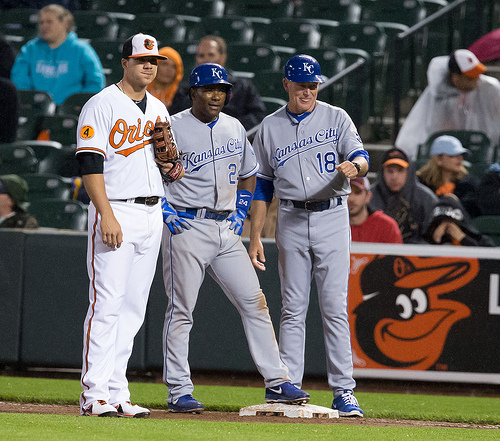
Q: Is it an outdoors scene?
A: Yes, it is outdoors.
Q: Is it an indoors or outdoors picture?
A: It is outdoors.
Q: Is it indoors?
A: No, it is outdoors.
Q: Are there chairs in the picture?
A: Yes, there is a chair.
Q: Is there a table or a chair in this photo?
A: Yes, there is a chair.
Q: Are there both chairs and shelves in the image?
A: No, there is a chair but no shelves.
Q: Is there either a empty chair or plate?
A: Yes, there is an empty chair.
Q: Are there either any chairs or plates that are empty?
A: Yes, the chair is empty.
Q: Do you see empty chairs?
A: Yes, there is an empty chair.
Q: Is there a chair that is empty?
A: Yes, there is a chair that is empty.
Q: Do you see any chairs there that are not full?
A: Yes, there is a empty chair.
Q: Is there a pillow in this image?
A: No, there are no pillows.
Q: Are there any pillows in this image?
A: No, there are no pillows.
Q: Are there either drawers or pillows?
A: No, there are no pillows or drawers.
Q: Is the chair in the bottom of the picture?
A: No, the chair is in the top of the image.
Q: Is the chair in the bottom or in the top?
A: The chair is in the top of the image.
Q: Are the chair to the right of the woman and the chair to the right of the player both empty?
A: Yes, both the chair and the chair are empty.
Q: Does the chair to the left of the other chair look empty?
A: Yes, the chair is empty.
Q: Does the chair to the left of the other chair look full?
A: No, the chair is empty.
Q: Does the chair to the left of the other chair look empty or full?
A: The chair is empty.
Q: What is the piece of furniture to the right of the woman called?
A: The piece of furniture is a chair.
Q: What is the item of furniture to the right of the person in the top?
A: The piece of furniture is a chair.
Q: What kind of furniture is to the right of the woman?
A: The piece of furniture is a chair.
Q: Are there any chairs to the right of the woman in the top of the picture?
A: Yes, there is a chair to the right of the woman.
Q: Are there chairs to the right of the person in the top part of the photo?
A: Yes, there is a chair to the right of the woman.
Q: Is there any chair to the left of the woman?
A: No, the chair is to the right of the woman.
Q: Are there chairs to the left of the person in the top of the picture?
A: No, the chair is to the right of the woman.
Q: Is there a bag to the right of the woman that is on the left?
A: No, there is a chair to the right of the woman.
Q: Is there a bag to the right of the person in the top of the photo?
A: No, there is a chair to the right of the woman.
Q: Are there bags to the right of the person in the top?
A: No, there is a chair to the right of the woman.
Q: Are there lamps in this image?
A: No, there are no lamps.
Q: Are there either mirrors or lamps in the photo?
A: No, there are no lamps or mirrors.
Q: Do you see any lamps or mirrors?
A: No, there are no lamps or mirrors.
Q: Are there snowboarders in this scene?
A: No, there are no snowboarders.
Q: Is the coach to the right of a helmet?
A: Yes, the coach is to the right of a helmet.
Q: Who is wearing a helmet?
A: The coach is wearing a helmet.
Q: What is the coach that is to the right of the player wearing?
A: The coach is wearing a helmet.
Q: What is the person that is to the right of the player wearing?
A: The coach is wearing a helmet.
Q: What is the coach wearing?
A: The coach is wearing a helmet.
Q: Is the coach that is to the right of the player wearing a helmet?
A: Yes, the coach is wearing a helmet.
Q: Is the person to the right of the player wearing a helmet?
A: Yes, the coach is wearing a helmet.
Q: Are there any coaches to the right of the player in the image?
A: Yes, there is a coach to the right of the player.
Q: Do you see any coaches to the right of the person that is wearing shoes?
A: Yes, there is a coach to the right of the player.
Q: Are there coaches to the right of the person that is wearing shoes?
A: Yes, there is a coach to the right of the player.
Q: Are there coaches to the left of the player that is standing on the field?
A: No, the coach is to the right of the player.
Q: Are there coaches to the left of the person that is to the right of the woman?
A: No, the coach is to the right of the player.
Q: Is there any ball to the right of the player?
A: No, there is a coach to the right of the player.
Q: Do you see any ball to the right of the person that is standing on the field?
A: No, there is a coach to the right of the player.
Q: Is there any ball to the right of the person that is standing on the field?
A: No, there is a coach to the right of the player.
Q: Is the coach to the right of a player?
A: Yes, the coach is to the right of a player.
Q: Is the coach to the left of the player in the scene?
A: No, the coach is to the right of the player.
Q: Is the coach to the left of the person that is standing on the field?
A: No, the coach is to the right of the player.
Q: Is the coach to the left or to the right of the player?
A: The coach is to the right of the player.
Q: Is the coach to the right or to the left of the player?
A: The coach is to the right of the player.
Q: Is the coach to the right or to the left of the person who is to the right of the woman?
A: The coach is to the right of the player.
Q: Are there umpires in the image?
A: No, there are no umpires.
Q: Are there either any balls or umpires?
A: No, there are no umpires or balls.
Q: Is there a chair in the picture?
A: Yes, there is a chair.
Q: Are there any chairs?
A: Yes, there is a chair.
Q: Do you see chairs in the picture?
A: Yes, there is a chair.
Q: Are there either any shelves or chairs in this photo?
A: Yes, there is a chair.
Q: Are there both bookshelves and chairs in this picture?
A: No, there is a chair but no bookshelves.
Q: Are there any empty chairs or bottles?
A: Yes, there is an empty chair.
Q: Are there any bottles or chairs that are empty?
A: Yes, the chair is empty.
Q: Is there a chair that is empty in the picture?
A: Yes, there is an empty chair.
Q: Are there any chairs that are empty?
A: Yes, there is a chair that is empty.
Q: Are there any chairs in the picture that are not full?
A: Yes, there is a empty chair.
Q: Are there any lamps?
A: No, there are no lamps.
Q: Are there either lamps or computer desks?
A: No, there are no lamps or computer desks.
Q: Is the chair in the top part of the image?
A: Yes, the chair is in the top of the image.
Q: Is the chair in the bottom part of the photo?
A: No, the chair is in the top of the image.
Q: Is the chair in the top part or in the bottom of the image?
A: The chair is in the top of the image.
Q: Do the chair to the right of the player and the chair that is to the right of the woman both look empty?
A: Yes, both the chair and the chair are empty.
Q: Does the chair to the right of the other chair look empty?
A: Yes, the chair is empty.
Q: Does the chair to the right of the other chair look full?
A: No, the chair is empty.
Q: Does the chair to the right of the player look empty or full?
A: The chair is empty.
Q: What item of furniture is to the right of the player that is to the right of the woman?
A: The piece of furniture is a chair.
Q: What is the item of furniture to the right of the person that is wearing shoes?
A: The piece of furniture is a chair.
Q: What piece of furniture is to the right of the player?
A: The piece of furniture is a chair.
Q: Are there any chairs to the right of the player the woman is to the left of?
A: Yes, there is a chair to the right of the player.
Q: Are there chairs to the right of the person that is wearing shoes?
A: Yes, there is a chair to the right of the player.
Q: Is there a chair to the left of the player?
A: No, the chair is to the right of the player.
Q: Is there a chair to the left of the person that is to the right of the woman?
A: No, the chair is to the right of the player.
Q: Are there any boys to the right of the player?
A: No, there is a chair to the right of the player.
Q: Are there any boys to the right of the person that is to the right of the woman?
A: No, there is a chair to the right of the player.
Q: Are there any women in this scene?
A: Yes, there is a woman.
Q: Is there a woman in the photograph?
A: Yes, there is a woman.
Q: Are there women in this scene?
A: Yes, there is a woman.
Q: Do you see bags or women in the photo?
A: Yes, there is a woman.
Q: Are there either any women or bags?
A: Yes, there is a woman.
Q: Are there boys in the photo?
A: No, there are no boys.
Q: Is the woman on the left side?
A: Yes, the woman is on the left of the image.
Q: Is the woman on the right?
A: No, the woman is on the left of the image.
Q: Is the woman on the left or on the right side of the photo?
A: The woman is on the left of the image.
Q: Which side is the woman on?
A: The woman is on the left of the image.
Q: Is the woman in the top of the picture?
A: Yes, the woman is in the top of the image.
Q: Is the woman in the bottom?
A: No, the woman is in the top of the image.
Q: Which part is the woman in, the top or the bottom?
A: The woman is in the top of the image.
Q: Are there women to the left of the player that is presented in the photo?
A: Yes, there is a woman to the left of the player.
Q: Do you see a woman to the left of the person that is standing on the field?
A: Yes, there is a woman to the left of the player.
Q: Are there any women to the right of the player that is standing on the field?
A: No, the woman is to the left of the player.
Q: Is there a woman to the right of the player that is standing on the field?
A: No, the woman is to the left of the player.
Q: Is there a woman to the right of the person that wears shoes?
A: No, the woman is to the left of the player.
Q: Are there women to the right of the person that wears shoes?
A: No, the woman is to the left of the player.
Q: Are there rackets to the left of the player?
A: No, there is a woman to the left of the player.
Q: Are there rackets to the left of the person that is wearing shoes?
A: No, there is a woman to the left of the player.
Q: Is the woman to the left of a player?
A: Yes, the woman is to the left of a player.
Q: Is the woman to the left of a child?
A: No, the woman is to the left of a player.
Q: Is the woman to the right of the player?
A: No, the woman is to the left of the player.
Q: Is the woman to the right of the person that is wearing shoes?
A: No, the woman is to the left of the player.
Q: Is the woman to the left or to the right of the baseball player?
A: The woman is to the left of the player.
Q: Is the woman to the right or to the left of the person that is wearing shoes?
A: The woman is to the left of the player.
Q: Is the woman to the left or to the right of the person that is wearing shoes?
A: The woman is to the left of the player.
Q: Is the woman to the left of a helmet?
A: Yes, the woman is to the left of a helmet.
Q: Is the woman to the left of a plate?
A: No, the woman is to the left of a helmet.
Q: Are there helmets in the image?
A: Yes, there is a helmet.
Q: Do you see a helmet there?
A: Yes, there is a helmet.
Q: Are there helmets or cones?
A: Yes, there is a helmet.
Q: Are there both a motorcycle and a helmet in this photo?
A: No, there is a helmet but no motorcycles.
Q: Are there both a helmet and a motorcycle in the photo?
A: No, there is a helmet but no motorcycles.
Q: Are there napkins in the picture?
A: No, there are no napkins.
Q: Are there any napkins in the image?
A: No, there are no napkins.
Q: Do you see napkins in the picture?
A: No, there are no napkins.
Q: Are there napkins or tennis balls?
A: No, there are no napkins or tennis balls.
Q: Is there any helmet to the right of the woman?
A: Yes, there is a helmet to the right of the woman.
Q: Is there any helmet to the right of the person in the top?
A: Yes, there is a helmet to the right of the woman.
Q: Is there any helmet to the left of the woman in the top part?
A: No, the helmet is to the right of the woman.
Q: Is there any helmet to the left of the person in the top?
A: No, the helmet is to the right of the woman.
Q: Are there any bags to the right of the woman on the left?
A: No, there is a helmet to the right of the woman.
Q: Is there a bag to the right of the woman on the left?
A: No, there is a helmet to the right of the woman.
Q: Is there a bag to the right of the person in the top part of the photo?
A: No, there is a helmet to the right of the woman.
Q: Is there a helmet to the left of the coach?
A: Yes, there is a helmet to the left of the coach.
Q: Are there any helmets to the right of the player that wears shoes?
A: Yes, there is a helmet to the right of the player.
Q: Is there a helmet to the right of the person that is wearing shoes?
A: Yes, there is a helmet to the right of the player.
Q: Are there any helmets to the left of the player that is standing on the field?
A: No, the helmet is to the right of the player.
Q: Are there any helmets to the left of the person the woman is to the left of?
A: No, the helmet is to the right of the player.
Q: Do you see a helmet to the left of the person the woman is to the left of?
A: No, the helmet is to the right of the player.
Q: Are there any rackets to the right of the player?
A: No, there is a helmet to the right of the player.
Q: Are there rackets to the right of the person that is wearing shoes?
A: No, there is a helmet to the right of the player.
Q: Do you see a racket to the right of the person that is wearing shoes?
A: No, there is a helmet to the right of the player.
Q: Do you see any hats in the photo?
A: Yes, there is a hat.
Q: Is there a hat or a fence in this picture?
A: Yes, there is a hat.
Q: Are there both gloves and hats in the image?
A: Yes, there are both a hat and gloves.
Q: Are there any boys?
A: No, there are no boys.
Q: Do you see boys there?
A: No, there are no boys.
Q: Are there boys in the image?
A: No, there are no boys.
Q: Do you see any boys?
A: No, there are no boys.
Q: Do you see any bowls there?
A: No, there are no bowls.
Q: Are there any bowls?
A: No, there are no bowls.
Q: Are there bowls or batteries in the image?
A: No, there are no bowls or batteries.